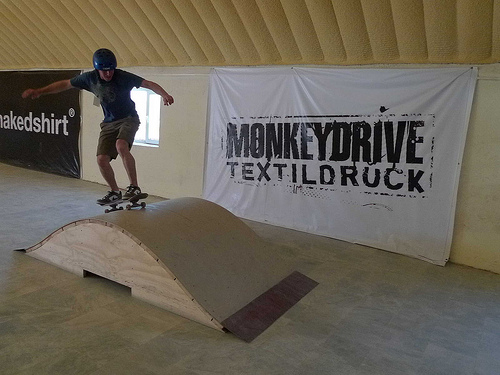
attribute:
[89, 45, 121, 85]
helmet — blue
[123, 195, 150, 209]
wheels — small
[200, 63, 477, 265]
sign — white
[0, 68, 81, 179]
signboard — big, black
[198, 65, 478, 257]
signboard — white